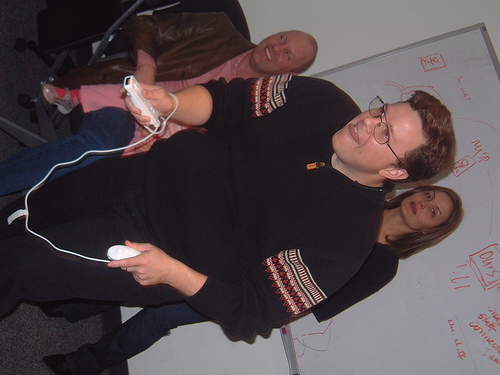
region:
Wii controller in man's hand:
[86, 58, 185, 134]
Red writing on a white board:
[468, 247, 498, 272]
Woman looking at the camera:
[402, 183, 462, 228]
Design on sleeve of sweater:
[249, 243, 339, 319]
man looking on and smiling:
[243, 29, 318, 71]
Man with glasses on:
[368, 81, 403, 151]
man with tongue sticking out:
[318, 92, 443, 167]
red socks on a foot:
[48, 80, 81, 113]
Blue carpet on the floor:
[25, 324, 50, 349]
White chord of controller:
[22, 170, 37, 244]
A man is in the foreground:
[3, 64, 466, 342]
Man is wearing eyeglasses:
[364, 76, 414, 179]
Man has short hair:
[379, 85, 455, 188]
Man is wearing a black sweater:
[145, 53, 395, 343]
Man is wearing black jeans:
[3, 145, 193, 316]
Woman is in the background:
[380, 173, 469, 274]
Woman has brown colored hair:
[373, 165, 467, 268]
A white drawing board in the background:
[271, 27, 496, 373]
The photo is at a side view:
[6, 1, 499, 373]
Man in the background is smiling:
[238, 10, 322, 85]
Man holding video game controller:
[20, 76, 182, 281]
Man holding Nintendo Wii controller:
[5, 73, 183, 268]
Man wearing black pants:
[1, 153, 193, 328]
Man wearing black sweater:
[142, 69, 391, 346]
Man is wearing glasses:
[367, 90, 414, 170]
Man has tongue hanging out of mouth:
[341, 117, 363, 148]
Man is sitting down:
[3, 5, 320, 200]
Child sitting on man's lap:
[42, 73, 207, 166]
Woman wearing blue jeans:
[37, 291, 227, 372]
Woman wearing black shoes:
[37, 299, 128, 374]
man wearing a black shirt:
[0, 73, 453, 338]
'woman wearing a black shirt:
[42, 182, 464, 373]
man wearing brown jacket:
[3, 7, 319, 206]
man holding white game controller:
[4, 78, 456, 344]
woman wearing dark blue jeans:
[21, 186, 463, 373]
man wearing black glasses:
[14, 79, 451, 343]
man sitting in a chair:
[0, 0, 318, 194]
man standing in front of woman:
[4, 75, 464, 373]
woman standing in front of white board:
[43, 182, 463, 373]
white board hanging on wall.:
[239, 20, 499, 372]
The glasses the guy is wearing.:
[370, 95, 407, 147]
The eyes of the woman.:
[424, 188, 436, 222]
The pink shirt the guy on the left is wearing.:
[181, 38, 251, 99]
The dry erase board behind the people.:
[295, 3, 498, 373]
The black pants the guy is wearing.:
[13, 163, 160, 298]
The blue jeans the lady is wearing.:
[37, 242, 206, 361]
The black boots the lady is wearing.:
[34, 291, 81, 371]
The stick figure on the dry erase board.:
[414, 45, 450, 75]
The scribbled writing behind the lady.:
[293, 319, 333, 374]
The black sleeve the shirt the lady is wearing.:
[337, 221, 392, 334]